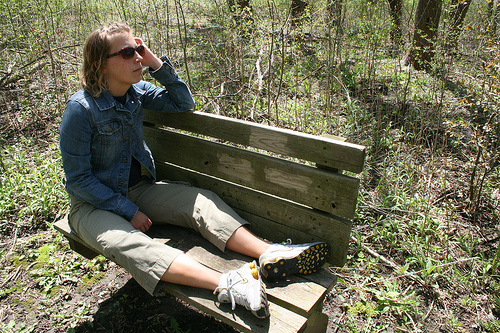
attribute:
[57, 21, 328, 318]
person — walking, enjoying, tan, sitting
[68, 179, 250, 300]
pants — tan, capri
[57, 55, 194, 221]
jacket — blue, denim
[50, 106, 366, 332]
bench — wooden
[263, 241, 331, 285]
shoe — white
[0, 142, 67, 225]
brush — short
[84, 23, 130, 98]
hair — brown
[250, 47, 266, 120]
branches — thin